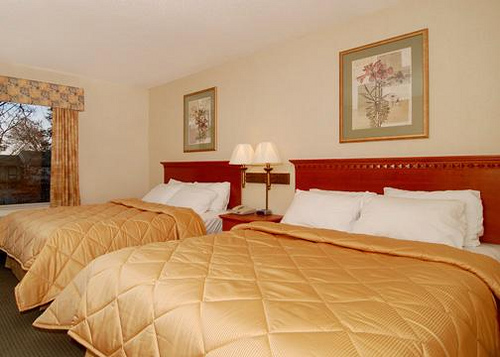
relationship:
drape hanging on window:
[51, 106, 80, 208] [1, 102, 54, 204]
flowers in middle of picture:
[356, 59, 405, 129] [338, 28, 429, 143]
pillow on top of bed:
[353, 192, 466, 253] [32, 156, 499, 355]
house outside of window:
[1, 149, 52, 185] [1, 102, 54, 204]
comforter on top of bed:
[32, 220, 498, 357] [32, 156, 499, 355]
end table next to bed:
[219, 213, 283, 232] [32, 156, 499, 355]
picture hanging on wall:
[338, 28, 429, 143] [150, 1, 499, 193]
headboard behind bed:
[287, 155, 499, 246] [32, 156, 499, 355]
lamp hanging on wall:
[251, 141, 282, 190] [150, 1, 499, 193]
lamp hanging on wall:
[228, 143, 255, 188] [150, 1, 499, 193]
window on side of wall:
[1, 102, 54, 204] [0, 58, 149, 217]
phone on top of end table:
[231, 205, 256, 216] [219, 213, 283, 232]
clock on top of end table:
[256, 209, 272, 216] [219, 213, 283, 232]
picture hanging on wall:
[182, 85, 218, 153] [150, 1, 499, 193]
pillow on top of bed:
[281, 190, 364, 235] [32, 156, 499, 355]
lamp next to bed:
[251, 141, 282, 190] [32, 156, 499, 355]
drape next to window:
[51, 106, 80, 208] [1, 102, 54, 204]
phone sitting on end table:
[231, 205, 256, 216] [219, 213, 283, 232]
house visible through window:
[1, 149, 52, 185] [1, 102, 54, 204]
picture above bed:
[338, 28, 429, 143] [32, 156, 499, 355]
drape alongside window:
[51, 106, 80, 208] [1, 102, 54, 204]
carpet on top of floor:
[1, 266, 86, 356] [0, 261, 85, 356]